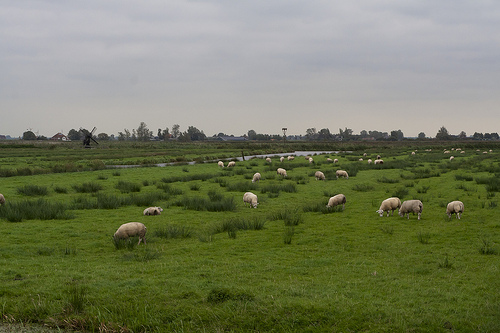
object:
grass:
[338, 272, 358, 291]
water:
[296, 150, 312, 153]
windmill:
[78, 124, 99, 148]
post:
[241, 150, 245, 161]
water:
[267, 153, 279, 155]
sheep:
[397, 198, 424, 220]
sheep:
[111, 221, 148, 247]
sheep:
[141, 204, 167, 215]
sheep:
[325, 194, 345, 213]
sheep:
[375, 194, 401, 217]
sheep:
[443, 199, 463, 221]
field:
[5, 138, 500, 332]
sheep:
[240, 190, 260, 209]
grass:
[11, 310, 30, 329]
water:
[156, 162, 163, 166]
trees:
[134, 118, 152, 140]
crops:
[116, 158, 123, 162]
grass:
[204, 241, 217, 254]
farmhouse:
[47, 132, 72, 142]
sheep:
[276, 167, 289, 175]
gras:
[281, 226, 295, 244]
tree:
[436, 127, 450, 141]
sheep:
[450, 155, 455, 162]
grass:
[8, 226, 25, 237]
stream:
[125, 144, 353, 165]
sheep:
[249, 173, 261, 184]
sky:
[10, 6, 491, 138]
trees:
[246, 129, 256, 138]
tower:
[282, 126, 289, 145]